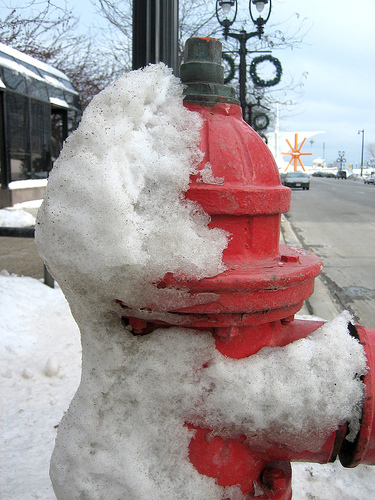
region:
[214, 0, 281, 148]
wreath Christmas decorations on streetlights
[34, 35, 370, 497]
red fire hydrant half covered with snow and ice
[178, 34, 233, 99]
top piece of fire hydrant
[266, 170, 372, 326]
city street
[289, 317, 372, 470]
fire hydrant outlet pipe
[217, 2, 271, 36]
streetlights fashioned like gas lamps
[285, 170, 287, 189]
car driving down city street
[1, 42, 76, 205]
business building store front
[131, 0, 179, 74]
green metal utility pole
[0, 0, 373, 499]
sunny winter day with clear streets and snowy sidewalks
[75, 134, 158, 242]
snow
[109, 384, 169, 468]
the white snow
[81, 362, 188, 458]
snow on the fire hydrant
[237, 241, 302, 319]
the fire hydrant is red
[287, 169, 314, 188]
a car in the street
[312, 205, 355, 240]
the street is grey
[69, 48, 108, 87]
tree branches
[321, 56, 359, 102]
a cloud that is white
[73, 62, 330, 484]
a fire hydrant with snow on it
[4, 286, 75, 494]
snow on the ground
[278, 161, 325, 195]
a car on the street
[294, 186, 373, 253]
the street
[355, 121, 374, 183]
a lamp post on the street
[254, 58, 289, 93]
a wreath hanging from the post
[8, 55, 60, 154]
a building next to the sidewalk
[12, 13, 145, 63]
trees behind the building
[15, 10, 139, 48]
the sky above the trees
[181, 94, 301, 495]
this is a hydrant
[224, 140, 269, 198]
the hydrant is red in color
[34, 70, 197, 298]
the hydrant is white in color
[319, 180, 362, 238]
this is the road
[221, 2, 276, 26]
this is the street light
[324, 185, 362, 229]
the road is clear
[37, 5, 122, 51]
this is the tree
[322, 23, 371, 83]
this is the sky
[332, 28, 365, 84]
the sky is clear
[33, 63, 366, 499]
snow on fire hydrant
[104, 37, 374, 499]
fire hydrant is red with black top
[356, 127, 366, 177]
light pole next to street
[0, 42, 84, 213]
building with glass front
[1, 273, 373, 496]
snow on sidewalk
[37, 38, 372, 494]
Red snow covered fire hydrant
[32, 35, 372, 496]
Red fire hydrant with snow on it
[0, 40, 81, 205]
Building with lots of windows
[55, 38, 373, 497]
Fire hydrant covered in snow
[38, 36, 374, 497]
Red hydrant covered in dirty snow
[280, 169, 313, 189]
A gray sedan on the side of the road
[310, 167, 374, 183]
Cars parked on the side of the road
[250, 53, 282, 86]
A festive handing green wreath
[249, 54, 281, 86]
A green decorative wreath hanging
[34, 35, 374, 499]
the fire hydrant is red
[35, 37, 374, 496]
the fire hydrant is covered in snow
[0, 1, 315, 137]
the tree branches are bare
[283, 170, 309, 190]
the car is parked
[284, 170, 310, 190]
the car is gray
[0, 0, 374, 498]
the sky above the hydrant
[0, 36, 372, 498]
the hydrant is surrounded by snow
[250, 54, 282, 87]
the wreath is round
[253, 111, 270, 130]
the wreath is round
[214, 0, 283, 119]
the wreaths are hanging from the street light